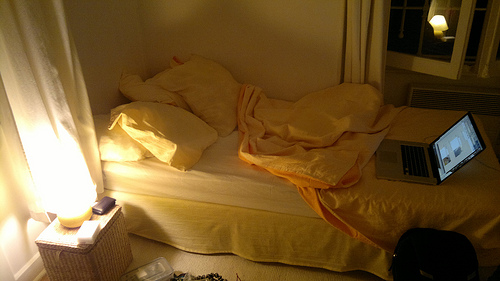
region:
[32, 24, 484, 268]
a messy bedroom area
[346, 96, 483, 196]
a laptop on the bed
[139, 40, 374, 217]
yellow sheets on a bed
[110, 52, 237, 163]
yellow pillow cases on the bed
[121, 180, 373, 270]
a yellow runner on the bed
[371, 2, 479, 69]
a light in another part of the room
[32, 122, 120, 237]
the light is on the nightstand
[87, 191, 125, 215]
an object on the nightstand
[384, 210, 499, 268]
an object in the room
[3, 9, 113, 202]
a white curtain on window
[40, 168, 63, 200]
white fabric on curtain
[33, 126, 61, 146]
white fabric on curtain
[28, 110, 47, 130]
white fabric on curtain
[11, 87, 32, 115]
white fabric on curtain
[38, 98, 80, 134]
white fabric on curtain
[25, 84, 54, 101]
white fabric on curtain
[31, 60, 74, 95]
white fabric on curtain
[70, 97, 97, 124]
white fabric on curtain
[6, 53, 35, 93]
white fabric on curtain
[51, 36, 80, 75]
white fabric on curtain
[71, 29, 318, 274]
Bed on the floor.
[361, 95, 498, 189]
Computer on the bed.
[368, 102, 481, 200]
Lap top on the bed.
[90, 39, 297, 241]
Pillows on the bed.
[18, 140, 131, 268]
Light on the night stand.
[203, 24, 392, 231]
Blanket on the bed.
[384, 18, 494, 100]
Window on the wall.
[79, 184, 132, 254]
Phone on the night stand.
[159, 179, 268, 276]
Skirt on the bed.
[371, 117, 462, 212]
Keys on the computer.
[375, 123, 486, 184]
the laptop on the bed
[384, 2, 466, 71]
the window is open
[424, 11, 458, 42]
reflection in the window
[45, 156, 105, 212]
lamp on the nightstand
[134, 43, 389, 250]
the bed is unmade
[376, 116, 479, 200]
the laptop is on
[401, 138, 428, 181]
keyboard of the laptop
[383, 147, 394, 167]
track pad of the laptop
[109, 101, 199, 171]
the pillow on the bed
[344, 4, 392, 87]
the curtain by the window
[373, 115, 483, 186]
laptop computer sitting on a bed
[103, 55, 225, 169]
pillows with yellow pillowcases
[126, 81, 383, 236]
yellow and white bedding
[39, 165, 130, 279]
wicker basket with a lamp on top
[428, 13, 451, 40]
reflection of a lamp in the window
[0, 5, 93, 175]
curtain hanging by the lamp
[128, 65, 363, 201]
unmade bed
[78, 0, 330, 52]
white wall behind the bed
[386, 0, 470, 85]
open window at night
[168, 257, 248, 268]
white carpeted floor